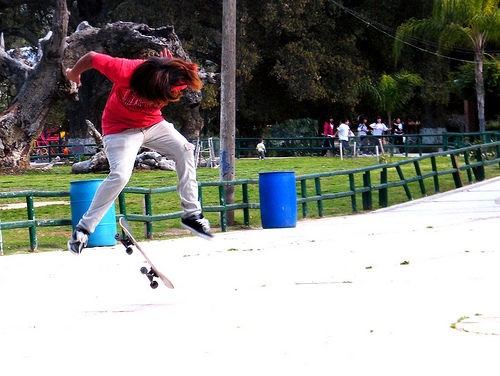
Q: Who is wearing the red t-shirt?
A: The boy.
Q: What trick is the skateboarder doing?
A: An ollie.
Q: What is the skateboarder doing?
A: Performing a trick.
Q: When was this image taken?
A: In the afternoon.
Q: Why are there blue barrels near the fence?
A: The are being used as garbage bins.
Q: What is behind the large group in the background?
A: Trees.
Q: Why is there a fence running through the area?
A: It keeps animals and vehicle out.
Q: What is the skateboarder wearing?
A: A t-shirt and jeans.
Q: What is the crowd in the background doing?
A: Talking to one another.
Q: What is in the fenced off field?
A: A large gnarled tree.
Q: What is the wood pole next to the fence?
A: A utility pole.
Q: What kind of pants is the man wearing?
A: Khaki pants.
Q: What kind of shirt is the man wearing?
A: A red short-sleeved shirt.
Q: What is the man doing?
A: Skateboarding.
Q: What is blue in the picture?
A: Two trash cans.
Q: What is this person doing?
A: Riding a skateboard.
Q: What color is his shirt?
A: It is red.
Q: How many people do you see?
A: At least seven.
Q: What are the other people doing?
A: They are talking.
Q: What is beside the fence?
A: Blue trash cans.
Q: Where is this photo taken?
A: A park.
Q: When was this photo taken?
A: During the day.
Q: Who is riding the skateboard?
A: A kid.